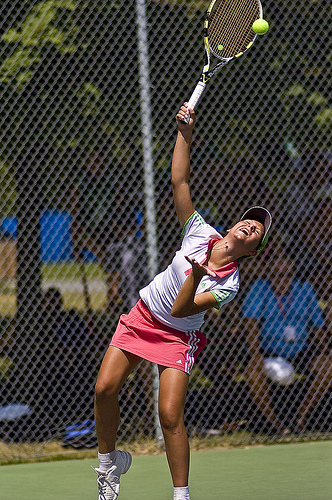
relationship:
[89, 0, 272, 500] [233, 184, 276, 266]
girl wearing cap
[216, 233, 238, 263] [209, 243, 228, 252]
neck on necklace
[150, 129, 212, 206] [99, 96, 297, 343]
arm on person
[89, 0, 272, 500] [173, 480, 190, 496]
girl wearing sock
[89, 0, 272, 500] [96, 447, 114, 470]
girl wearing sock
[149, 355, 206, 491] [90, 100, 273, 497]
leg of a person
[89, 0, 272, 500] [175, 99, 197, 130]
girl has hand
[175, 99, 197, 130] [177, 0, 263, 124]
hand holding racket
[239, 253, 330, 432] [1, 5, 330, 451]
man behind fence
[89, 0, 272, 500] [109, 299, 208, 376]
girl wearing pink shorts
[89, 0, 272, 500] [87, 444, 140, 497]
girl wearing shoe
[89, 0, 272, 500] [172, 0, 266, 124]
girl holding racket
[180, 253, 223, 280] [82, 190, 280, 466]
hand of woman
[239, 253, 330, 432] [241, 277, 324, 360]
man wearing blue shirt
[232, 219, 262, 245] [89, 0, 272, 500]
face of girl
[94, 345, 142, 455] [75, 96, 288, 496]
leg of girl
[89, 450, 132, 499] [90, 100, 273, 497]
feet of person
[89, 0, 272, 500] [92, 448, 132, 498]
girl wearing shoes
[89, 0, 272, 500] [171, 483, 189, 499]
girl wearing shoes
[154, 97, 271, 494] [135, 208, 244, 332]
girl wearing shirt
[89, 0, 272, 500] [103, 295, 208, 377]
girl wearing pink shorts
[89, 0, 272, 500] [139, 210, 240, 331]
girl wearing shirt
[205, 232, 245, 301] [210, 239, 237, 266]
necklace on neck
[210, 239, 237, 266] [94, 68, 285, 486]
neck of girl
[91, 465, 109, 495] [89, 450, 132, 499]
laces on feet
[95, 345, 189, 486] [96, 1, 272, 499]
leg of person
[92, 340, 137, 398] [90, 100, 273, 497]
thigh of person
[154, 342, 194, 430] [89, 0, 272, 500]
thigh of girl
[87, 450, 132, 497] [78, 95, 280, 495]
feet of person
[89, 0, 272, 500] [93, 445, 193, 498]
girl wearing shoes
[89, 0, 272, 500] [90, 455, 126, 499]
girl wearing shoes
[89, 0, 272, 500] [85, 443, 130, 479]
girl wearing shoes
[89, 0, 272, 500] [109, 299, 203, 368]
girl wearing skirt